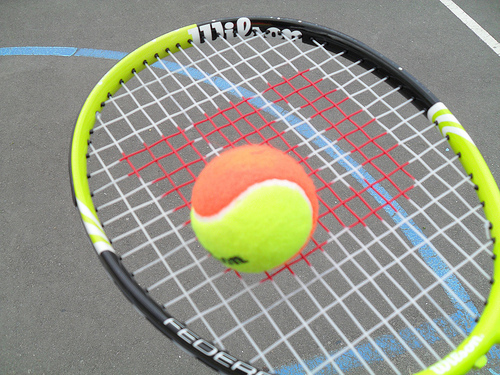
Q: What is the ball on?
A: Net.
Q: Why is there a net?
A: To hit.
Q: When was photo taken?
A: Daytime.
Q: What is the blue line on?
A: Court.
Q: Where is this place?
A: Tennis court.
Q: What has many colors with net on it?
A: Racket.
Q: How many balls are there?
A: One.